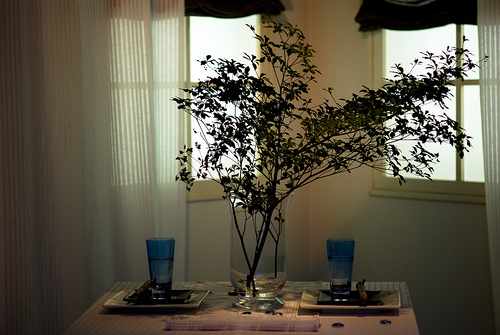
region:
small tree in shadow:
[357, 71, 454, 151]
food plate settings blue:
[129, 239, 196, 312]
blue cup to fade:
[324, 235, 358, 297]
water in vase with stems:
[204, 174, 304, 334]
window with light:
[80, 9, 279, 204]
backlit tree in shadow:
[358, 44, 474, 153]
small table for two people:
[64, 245, 433, 332]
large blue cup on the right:
[312, 226, 362, 298]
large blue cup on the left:
[144, 229, 194, 305]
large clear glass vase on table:
[224, 170, 300, 331]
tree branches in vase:
[223, 60, 457, 287]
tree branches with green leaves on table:
[210, 50, 396, 255]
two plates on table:
[288, 271, 414, 328]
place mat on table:
[171, 306, 316, 333]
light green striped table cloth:
[93, 308, 150, 334]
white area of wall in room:
[425, 235, 491, 295]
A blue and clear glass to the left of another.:
[142, 236, 175, 301]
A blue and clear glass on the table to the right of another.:
[325, 236, 355, 300]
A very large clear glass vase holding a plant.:
[227, 185, 288, 310]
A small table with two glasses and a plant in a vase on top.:
[52, 278, 423, 334]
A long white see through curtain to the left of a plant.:
[1, 0, 191, 331]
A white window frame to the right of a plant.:
[367, 7, 491, 207]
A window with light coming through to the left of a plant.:
[88, 3, 259, 200]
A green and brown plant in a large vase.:
[166, 11, 491, 293]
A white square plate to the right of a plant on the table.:
[297, 285, 400, 313]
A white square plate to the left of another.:
[100, 283, 211, 313]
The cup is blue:
[142, 233, 177, 306]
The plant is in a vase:
[188, 28, 471, 303]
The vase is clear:
[218, 192, 290, 317]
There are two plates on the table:
[105, 232, 403, 317]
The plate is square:
[296, 282, 401, 313]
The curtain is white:
[3, 3, 188, 314]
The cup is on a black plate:
[312, 232, 378, 302]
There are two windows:
[83, 1, 491, 216]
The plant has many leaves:
[178, 11, 468, 311]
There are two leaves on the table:
[328, 312, 393, 332]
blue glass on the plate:
[319, 233, 356, 300]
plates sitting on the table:
[297, 283, 402, 322]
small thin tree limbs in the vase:
[137, 16, 456, 225]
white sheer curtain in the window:
[19, 28, 189, 188]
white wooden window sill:
[376, 169, 491, 214]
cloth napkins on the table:
[157, 305, 335, 333]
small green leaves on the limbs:
[321, 94, 382, 139]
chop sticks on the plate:
[348, 268, 371, 307]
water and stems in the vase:
[229, 200, 287, 299]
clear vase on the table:
[222, 200, 302, 334]